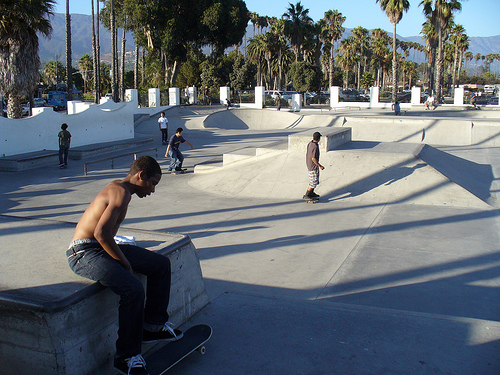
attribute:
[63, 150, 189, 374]
teenager — sitting, topless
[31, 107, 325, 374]
men — skateboarding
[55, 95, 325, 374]
boys — skateboarding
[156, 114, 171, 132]
shirt — white, brown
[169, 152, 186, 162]
knees — bending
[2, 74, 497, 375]
park — skate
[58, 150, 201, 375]
boy — black, shirtless, ready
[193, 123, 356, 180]
stairs — concrete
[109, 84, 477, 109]
plinths — white, concrete, surrounding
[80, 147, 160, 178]
rail — metal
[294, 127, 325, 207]
boy — skating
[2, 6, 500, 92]
hills — mountainous